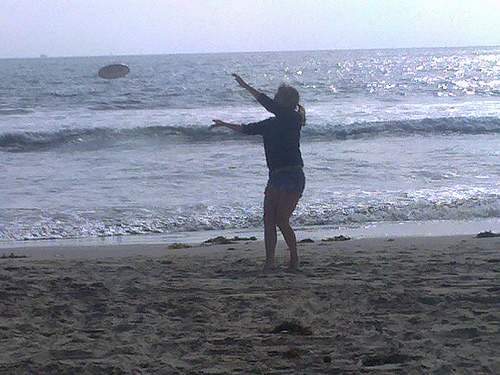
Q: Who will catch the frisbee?
A: The woman.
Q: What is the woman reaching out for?
A: A frisbee.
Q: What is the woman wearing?
A: Shorts, long-sleeve shirt.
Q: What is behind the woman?
A: The ocean.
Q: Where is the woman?
A: On the beach.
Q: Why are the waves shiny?
A: Reflecting sunlight.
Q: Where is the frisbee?
A: In front of the woman.